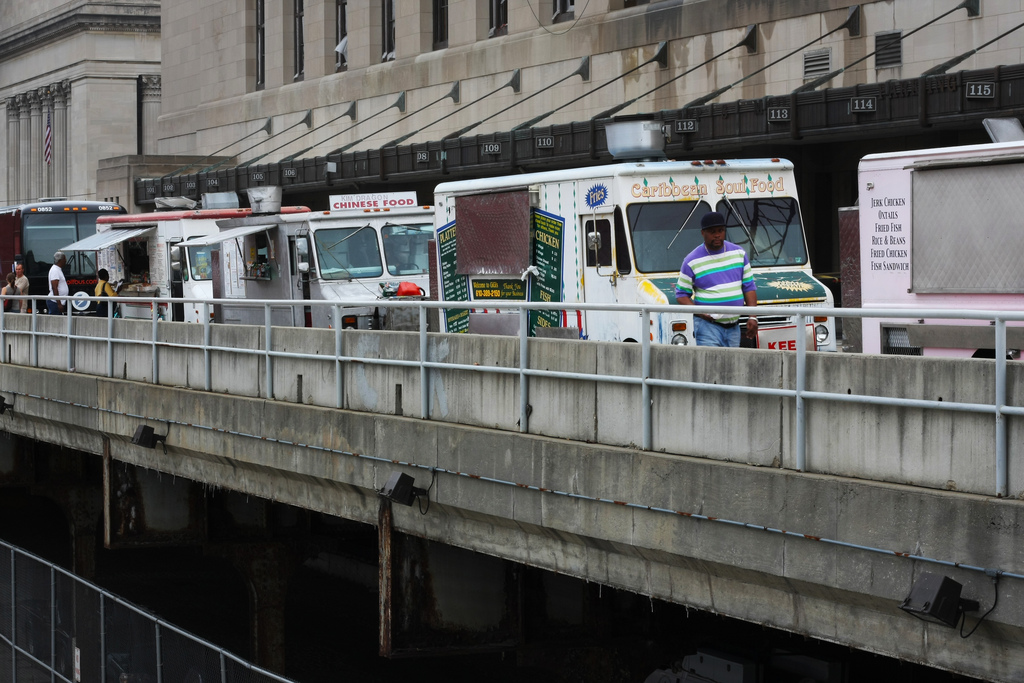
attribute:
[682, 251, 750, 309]
shirt — striped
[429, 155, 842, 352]
truck — food truck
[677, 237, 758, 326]
shirt — purple striped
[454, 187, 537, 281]
window — Closed